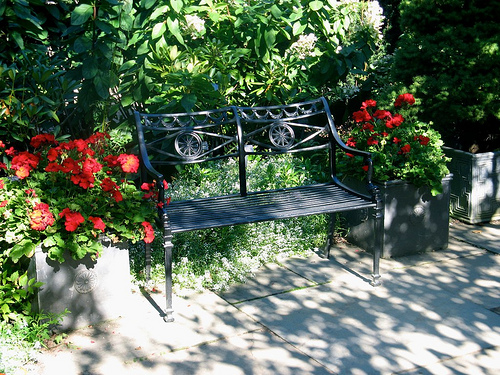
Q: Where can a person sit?
A: Bench.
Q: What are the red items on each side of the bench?
A: Flowers.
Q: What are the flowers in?
A: Planters.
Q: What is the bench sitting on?
A: Concrete.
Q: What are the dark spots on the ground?
A: Shadows.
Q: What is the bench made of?
A: Metal.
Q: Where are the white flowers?
A: Behind the bench.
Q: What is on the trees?
A: Leaves.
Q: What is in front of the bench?
A: Sidewalk.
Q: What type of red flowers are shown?
A: Roses.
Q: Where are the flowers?
A: Next to the bench.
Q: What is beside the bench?
A: Planters with flowers.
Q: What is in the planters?
A: Flowers.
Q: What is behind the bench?
A: Plants.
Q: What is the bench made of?
A: Metal.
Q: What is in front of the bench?
A: Pavement.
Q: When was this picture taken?
A: Daytime.